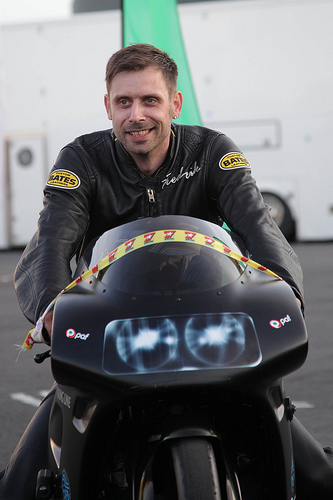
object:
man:
[11, 40, 307, 349]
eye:
[142, 96, 160, 106]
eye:
[116, 97, 131, 108]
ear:
[171, 90, 183, 120]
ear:
[103, 93, 112, 121]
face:
[109, 65, 171, 155]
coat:
[12, 122, 306, 327]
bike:
[0, 184, 333, 500]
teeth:
[138, 129, 143, 136]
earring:
[174, 115, 178, 120]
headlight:
[183, 313, 247, 368]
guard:
[147, 420, 225, 448]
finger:
[44, 317, 52, 340]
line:
[9, 386, 42, 405]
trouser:
[276, 411, 333, 499]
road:
[0, 236, 333, 499]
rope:
[14, 329, 36, 364]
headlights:
[115, 315, 179, 373]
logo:
[65, 327, 91, 341]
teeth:
[134, 131, 137, 135]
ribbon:
[23, 228, 284, 354]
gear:
[21, 310, 55, 365]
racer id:
[160, 160, 201, 191]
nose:
[129, 100, 147, 124]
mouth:
[124, 126, 157, 142]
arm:
[12, 143, 96, 342]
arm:
[206, 133, 304, 301]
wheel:
[164, 434, 225, 500]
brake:
[32, 347, 51, 369]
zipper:
[147, 187, 157, 205]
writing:
[160, 160, 202, 190]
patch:
[46, 168, 81, 191]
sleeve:
[10, 138, 93, 327]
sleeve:
[208, 131, 307, 317]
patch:
[218, 151, 251, 171]